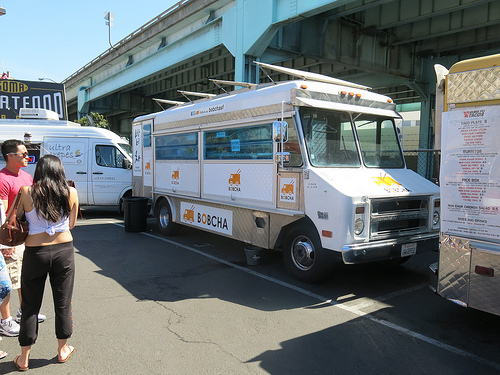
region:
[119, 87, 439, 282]
the bus is parked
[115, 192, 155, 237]
trash can beside the bus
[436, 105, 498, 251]
menu on the bus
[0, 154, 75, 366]
woman wearing a purse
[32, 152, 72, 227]
her hair is long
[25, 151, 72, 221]
her hair is brown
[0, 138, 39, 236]
man wearing pink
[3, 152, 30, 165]
man wearing sunglasses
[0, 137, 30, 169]
man's hair is black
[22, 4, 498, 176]
the buses are under the overpass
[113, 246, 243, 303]
shadow on the ground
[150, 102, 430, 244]
a food truck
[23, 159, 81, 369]
a women standing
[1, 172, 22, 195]
man wearing a red shirt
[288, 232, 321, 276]
front tire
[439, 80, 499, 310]
a food truck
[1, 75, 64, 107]
a sign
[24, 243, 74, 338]
women wearing black pants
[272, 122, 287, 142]
mirror on the food truck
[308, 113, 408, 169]
the windshied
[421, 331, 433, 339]
part of a shadow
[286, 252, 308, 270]
edge of a wheel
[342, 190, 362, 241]
front of a car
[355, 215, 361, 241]
light of a truck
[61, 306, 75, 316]
back of a woman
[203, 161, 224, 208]
side of a truck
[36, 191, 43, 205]
part of a hair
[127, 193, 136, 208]
edge of a bin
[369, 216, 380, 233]
side of a truck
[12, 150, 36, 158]
dark black sunglasses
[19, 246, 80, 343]
a woman's black pants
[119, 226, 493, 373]
a long white line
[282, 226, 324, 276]
the wheel of a truck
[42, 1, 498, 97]
part of a bridge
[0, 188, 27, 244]
a woman's purse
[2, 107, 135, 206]
part of a white van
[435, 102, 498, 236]
a large food menu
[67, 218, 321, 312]
a shadow of a truck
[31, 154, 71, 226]
a woman's black hair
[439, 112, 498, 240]
row of white signs on back of truck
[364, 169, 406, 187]
design on hood of truck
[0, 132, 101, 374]
group of people standing beside truck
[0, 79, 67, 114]
large sign behind truck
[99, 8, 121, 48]
silver metal traffic signs on overpass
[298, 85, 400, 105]
row of orange lights on top of truck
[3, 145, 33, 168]
man in dark sunglasses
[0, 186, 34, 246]
brown purse on shoulder of woman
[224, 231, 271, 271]
blue bucket sitting under truck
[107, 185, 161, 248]
black plastic trash can